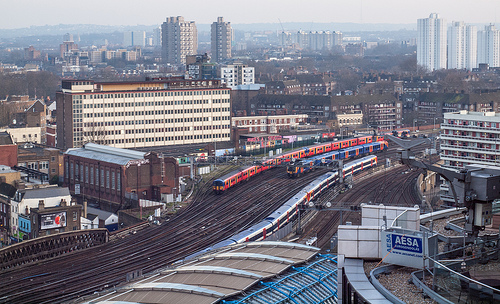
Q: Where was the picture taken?
A: In a city.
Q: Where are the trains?
A: On the tracks in the center of the picture.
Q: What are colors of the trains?
A: Red and blue.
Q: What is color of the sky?
A: Gray.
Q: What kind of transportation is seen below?
A: Trains.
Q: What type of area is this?
A: Urban.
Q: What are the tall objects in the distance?
A: Skyscrapers.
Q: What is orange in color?
A: One of the trains.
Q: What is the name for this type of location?
A: City.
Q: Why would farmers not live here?
A: No place to plant crops.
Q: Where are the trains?
A: On tracks.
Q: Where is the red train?
A: On left.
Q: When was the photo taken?
A: Daytime.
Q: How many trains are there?
A: Two.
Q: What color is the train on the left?
A: Orange and blue.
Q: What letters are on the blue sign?
A: AESA.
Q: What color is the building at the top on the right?
A: White.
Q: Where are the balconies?
A: Right, middle of the image.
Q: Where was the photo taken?
A: Overlooking a railroad.